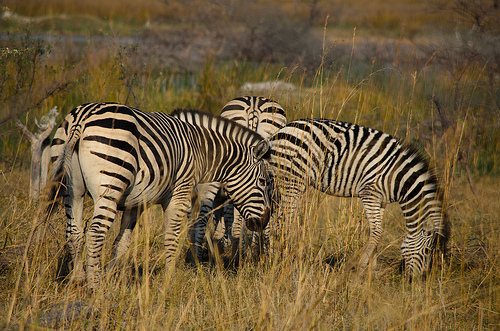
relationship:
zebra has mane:
[41, 101, 274, 293] [170, 106, 268, 158]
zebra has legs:
[41, 101, 274, 293] [84, 194, 118, 290]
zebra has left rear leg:
[41, 101, 274, 293] [63, 181, 91, 288]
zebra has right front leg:
[41, 101, 274, 293] [161, 184, 194, 280]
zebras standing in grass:
[43, 92, 458, 291] [5, 0, 498, 330]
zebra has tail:
[41, 101, 274, 293] [39, 124, 83, 225]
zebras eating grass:
[43, 92, 458, 291] [5, 0, 498, 330]